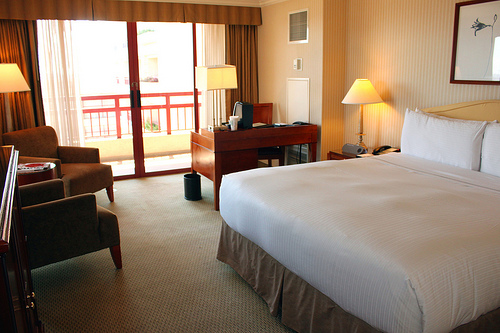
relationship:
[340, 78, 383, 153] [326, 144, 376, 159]
lamp on night stand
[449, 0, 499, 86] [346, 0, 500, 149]
picture on wall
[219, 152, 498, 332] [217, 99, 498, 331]
sheet on bed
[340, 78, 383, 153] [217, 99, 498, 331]
lamp next to bed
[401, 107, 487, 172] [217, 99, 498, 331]
pillow on bed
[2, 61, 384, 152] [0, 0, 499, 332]
lamps in room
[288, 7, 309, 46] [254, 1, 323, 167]
vent on wall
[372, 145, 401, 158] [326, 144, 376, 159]
phone on night stand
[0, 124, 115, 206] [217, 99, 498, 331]
chair across bed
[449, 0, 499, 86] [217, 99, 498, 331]
picture above bed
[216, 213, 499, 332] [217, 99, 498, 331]
bed skirt on bed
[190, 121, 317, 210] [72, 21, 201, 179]
desk in front of door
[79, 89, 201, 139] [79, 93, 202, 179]
railing on balcony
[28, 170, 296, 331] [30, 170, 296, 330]
carpet on floor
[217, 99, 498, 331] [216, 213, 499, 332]
bed has a bed skirt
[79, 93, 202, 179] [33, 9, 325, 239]
balcony in background